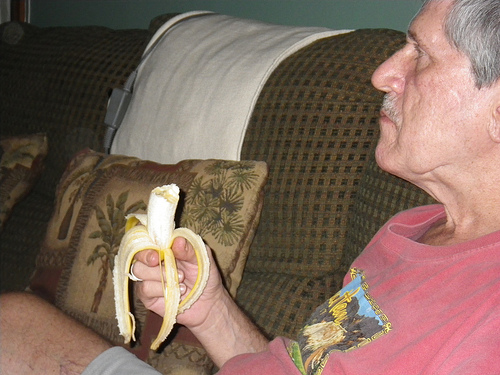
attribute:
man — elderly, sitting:
[0, 2, 499, 374]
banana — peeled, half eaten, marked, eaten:
[112, 182, 211, 351]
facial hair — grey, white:
[380, 93, 404, 135]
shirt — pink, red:
[208, 203, 499, 373]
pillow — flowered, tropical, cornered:
[27, 146, 267, 374]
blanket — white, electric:
[100, 7, 356, 165]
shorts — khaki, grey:
[73, 347, 175, 375]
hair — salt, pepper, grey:
[440, 0, 500, 86]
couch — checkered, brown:
[1, 20, 455, 373]